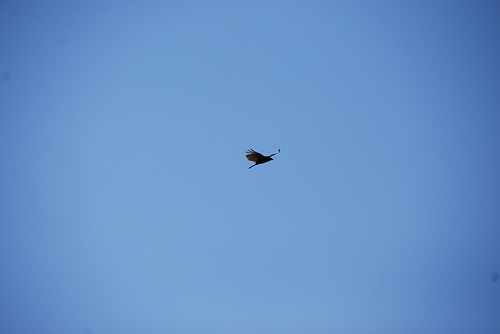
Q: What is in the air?
A: Bird.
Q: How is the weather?
A: Clear.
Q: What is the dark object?
A: Bird.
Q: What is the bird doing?
A: Flying.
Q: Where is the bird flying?
A: In the sky.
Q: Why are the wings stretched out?
A: To fly.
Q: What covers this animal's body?
A: Feathers.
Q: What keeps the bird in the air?
A: Wings.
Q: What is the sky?
A: Clear.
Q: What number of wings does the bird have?
A: 2.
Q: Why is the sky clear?
A: No clouds.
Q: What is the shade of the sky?
A: Blue.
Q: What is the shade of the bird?
A: Brown.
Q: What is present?
A: A bird.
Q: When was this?
A: Daytime.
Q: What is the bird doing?
A: Flying.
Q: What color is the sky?
A: Blue.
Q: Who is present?
A: Nobody.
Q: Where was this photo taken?
A: Open space.